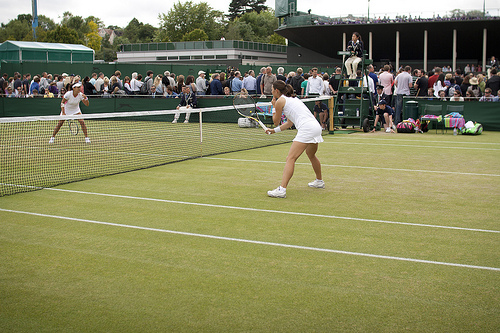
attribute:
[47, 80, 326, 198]
players — women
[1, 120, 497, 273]
tennis court — green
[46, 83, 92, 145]
player — ready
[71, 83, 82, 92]
hat — white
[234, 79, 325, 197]
player — ready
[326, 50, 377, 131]
ladder — green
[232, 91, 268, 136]
tennis racket — black, white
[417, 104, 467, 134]
chairs — green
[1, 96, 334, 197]
net — black, white, large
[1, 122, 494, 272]
lines — white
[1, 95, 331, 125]
top of net — white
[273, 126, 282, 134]
wristband — white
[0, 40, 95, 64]
building — green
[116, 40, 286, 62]
building — white, green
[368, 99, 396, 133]
ball shagger — ready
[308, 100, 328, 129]
ball shagger — ready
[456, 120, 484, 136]
bag — green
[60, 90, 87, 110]
shirt — white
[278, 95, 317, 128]
shirt — white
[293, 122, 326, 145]
skirt — white